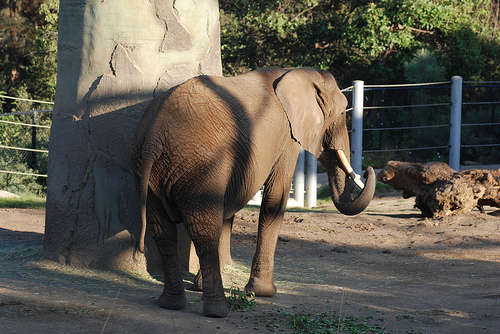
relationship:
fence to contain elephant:
[1, 75, 498, 211] [130, 65, 377, 317]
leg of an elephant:
[184, 212, 238, 319] [113, 49, 385, 323]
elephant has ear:
[130, 65, 377, 317] [273, 64, 320, 159]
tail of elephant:
[125, 127, 162, 277] [113, 49, 385, 323]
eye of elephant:
[341, 111, 344, 114] [136, 57, 386, 321]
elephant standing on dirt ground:
[139, 41, 381, 263] [284, 213, 484, 332]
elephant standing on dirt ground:
[130, 65, 377, 317] [284, 213, 484, 332]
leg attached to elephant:
[178, 152, 232, 316] [130, 65, 377, 317]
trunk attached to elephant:
[318, 114, 376, 216] [129, 63, 269, 245]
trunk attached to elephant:
[323, 143, 380, 225] [118, 60, 400, 311]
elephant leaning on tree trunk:
[130, 65, 377, 317] [43, 1, 138, 266]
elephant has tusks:
[130, 65, 377, 317] [337, 146, 369, 191]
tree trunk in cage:
[375, 157, 498, 224] [2, 75, 496, 330]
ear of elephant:
[272, 66, 329, 161] [113, 49, 385, 323]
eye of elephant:
[336, 101, 350, 123] [63, 30, 428, 303]